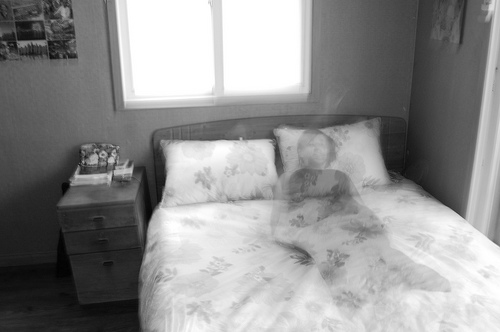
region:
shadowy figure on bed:
[266, 112, 477, 330]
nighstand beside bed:
[58, 176, 158, 301]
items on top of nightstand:
[65, 134, 151, 194]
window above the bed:
[120, 4, 308, 99]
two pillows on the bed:
[165, 124, 396, 200]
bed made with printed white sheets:
[143, 134, 498, 327]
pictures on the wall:
[2, 4, 79, 70]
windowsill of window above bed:
[113, 2, 310, 103]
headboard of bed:
[143, 115, 412, 191]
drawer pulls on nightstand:
[88, 212, 125, 282]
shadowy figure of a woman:
[275, 131, 450, 314]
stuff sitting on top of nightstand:
[67, 139, 141, 191]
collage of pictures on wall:
[5, 1, 83, 64]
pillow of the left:
[152, 134, 282, 201]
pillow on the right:
[282, 114, 397, 192]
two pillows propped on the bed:
[155, 117, 396, 204]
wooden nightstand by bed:
[59, 182, 150, 304]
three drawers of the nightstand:
[61, 209, 143, 299]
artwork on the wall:
[423, 2, 470, 52]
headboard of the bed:
[148, 121, 415, 186]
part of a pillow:
[202, 155, 280, 229]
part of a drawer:
[91, 194, 141, 227]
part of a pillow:
[178, 121, 220, 171]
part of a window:
[178, 38, 205, 81]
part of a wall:
[0, 156, 50, 213]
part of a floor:
[38, 293, 61, 313]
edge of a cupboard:
[101, 180, 116, 195]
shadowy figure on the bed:
[277, 125, 476, 320]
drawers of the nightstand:
[65, 208, 142, 299]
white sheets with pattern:
[159, 138, 489, 330]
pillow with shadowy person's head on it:
[284, 122, 395, 187]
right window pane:
[220, 2, 307, 93]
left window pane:
[125, 0, 217, 100]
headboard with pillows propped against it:
[150, 117, 415, 207]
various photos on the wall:
[3, 2, 92, 76]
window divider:
[209, 5, 230, 94]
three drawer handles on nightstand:
[86, 214, 116, 273]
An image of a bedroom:
[1, 3, 496, 328]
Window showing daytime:
[98, 2, 321, 102]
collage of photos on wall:
[0, 0, 75, 67]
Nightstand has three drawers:
[56, 183, 148, 303]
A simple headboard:
[148, 107, 413, 159]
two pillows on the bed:
[158, 121, 388, 194]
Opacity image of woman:
[274, 128, 369, 254]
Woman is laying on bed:
[272, 126, 375, 261]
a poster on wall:
[419, 1, 466, 48]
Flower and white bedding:
[148, 216, 276, 323]